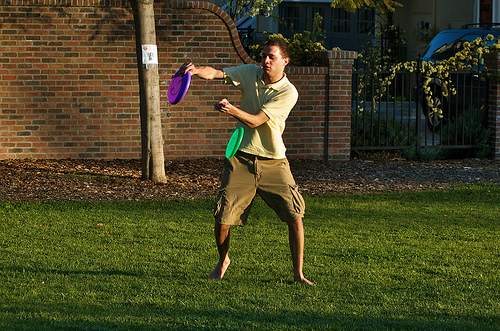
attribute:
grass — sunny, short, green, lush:
[1, 181, 498, 329]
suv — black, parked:
[418, 17, 499, 129]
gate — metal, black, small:
[349, 52, 488, 155]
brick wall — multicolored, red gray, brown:
[0, 0, 359, 160]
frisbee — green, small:
[222, 127, 245, 159]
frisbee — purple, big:
[165, 60, 192, 104]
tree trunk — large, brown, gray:
[128, 1, 169, 183]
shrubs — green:
[349, 102, 491, 157]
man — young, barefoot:
[181, 37, 316, 287]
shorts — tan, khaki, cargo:
[213, 150, 305, 225]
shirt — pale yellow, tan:
[219, 63, 300, 160]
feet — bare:
[210, 253, 317, 288]